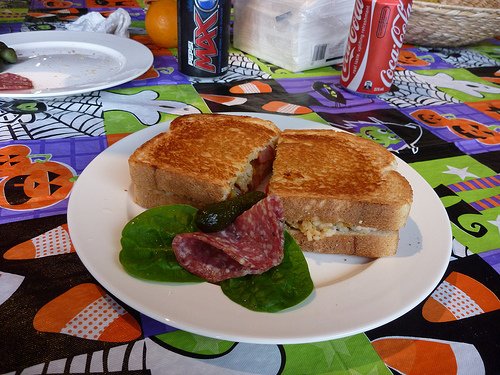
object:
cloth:
[1, 0, 500, 374]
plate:
[64, 107, 455, 347]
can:
[339, 1, 404, 94]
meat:
[169, 199, 286, 283]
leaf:
[114, 198, 270, 284]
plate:
[1, 26, 148, 102]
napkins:
[231, 2, 350, 71]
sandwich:
[120, 108, 415, 264]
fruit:
[143, 1, 182, 50]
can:
[174, 1, 232, 79]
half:
[124, 106, 279, 214]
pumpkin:
[411, 103, 451, 131]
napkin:
[63, 6, 130, 40]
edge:
[141, 277, 405, 350]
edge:
[268, 190, 411, 231]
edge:
[228, 281, 318, 314]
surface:
[126, 111, 276, 188]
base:
[339, 83, 397, 97]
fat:
[296, 218, 353, 241]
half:
[262, 122, 419, 260]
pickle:
[195, 190, 265, 232]